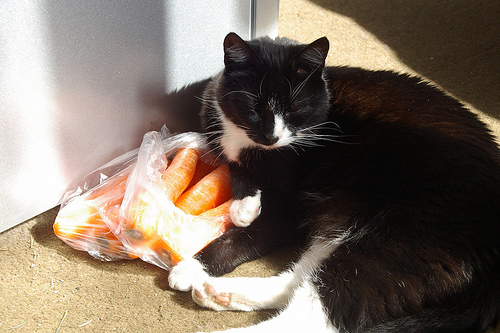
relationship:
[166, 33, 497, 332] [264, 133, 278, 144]
cat has nose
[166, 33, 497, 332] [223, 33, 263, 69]
cat has ear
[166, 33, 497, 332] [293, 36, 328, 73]
cat has ear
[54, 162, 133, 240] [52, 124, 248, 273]
carrot in bag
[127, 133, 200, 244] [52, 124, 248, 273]
carrot in bag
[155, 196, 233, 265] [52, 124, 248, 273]
carrot in bag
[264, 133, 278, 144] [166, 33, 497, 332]
nose on cat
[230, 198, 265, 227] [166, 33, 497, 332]
paws on cat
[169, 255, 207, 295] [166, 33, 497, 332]
paw on cat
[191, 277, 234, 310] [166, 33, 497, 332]
paw on cat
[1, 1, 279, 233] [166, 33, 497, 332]
fridge by cat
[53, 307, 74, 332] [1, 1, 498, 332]
twig on carpet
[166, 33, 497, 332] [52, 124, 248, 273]
cat by bag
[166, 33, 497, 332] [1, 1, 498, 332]
cat on floor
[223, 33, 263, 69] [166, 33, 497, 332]
ear on cat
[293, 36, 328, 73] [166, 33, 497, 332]
ear on cat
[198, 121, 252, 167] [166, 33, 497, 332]
whiskers on cat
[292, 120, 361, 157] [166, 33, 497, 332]
whiskers on cat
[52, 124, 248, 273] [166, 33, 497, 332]
bag by cat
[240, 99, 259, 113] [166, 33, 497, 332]
eye on cat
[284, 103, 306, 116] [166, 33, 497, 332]
eye on cat